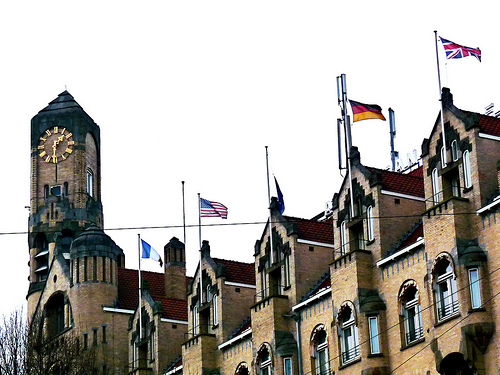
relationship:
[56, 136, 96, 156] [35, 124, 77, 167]
numerals on clock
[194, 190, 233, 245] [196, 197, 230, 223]
flag of america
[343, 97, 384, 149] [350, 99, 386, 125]
flag of germany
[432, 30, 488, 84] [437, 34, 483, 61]
flag of great britain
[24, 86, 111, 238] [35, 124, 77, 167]
tower has clock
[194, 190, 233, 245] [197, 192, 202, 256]
flag on a flagpole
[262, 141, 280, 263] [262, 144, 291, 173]
pole has no flag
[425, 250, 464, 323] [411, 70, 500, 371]
window along building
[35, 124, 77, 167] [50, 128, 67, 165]
"clock with hands at 1:30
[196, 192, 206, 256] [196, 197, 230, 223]
flagpole has american flag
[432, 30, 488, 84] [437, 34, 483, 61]
flag of united kingdom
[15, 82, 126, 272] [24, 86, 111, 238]
clocktower made of bricks and metal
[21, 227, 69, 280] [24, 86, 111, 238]
parapet attached to tower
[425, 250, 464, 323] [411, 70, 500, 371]
window built into brick building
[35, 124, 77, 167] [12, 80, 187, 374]
clock on building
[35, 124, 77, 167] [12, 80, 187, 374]
clock outside building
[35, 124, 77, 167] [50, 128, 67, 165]
clock with golden arms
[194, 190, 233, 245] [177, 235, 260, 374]
flag on top building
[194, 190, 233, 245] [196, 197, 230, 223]
flag with red stripes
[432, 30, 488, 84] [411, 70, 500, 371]
british flag on building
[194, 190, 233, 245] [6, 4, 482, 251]
flag flying in air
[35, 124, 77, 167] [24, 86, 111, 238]
clock at top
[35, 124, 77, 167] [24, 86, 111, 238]
clock on top of tower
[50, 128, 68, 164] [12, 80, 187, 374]
1:30 above building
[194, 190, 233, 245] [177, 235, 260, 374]
american flag on top building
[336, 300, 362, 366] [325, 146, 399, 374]
window in front of building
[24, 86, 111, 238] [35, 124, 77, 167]
tower has a clock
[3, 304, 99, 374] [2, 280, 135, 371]
tree in front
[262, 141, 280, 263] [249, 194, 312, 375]
pole on top of building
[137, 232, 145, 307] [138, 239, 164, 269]
pole has american flag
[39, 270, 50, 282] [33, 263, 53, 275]
window with awning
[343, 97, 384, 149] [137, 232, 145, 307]
flag on pole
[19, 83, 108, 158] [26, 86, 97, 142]
stone pillar on roof